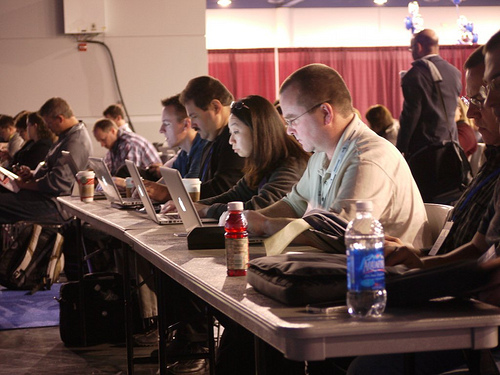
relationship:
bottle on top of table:
[221, 198, 251, 278] [51, 192, 498, 374]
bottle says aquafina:
[343, 198, 387, 319] [359, 258, 384, 271]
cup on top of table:
[77, 168, 99, 204] [51, 192, 498, 374]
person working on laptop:
[218, 62, 432, 250] [156, 162, 263, 245]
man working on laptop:
[180, 75, 240, 203] [122, 158, 219, 224]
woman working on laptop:
[189, 94, 308, 227] [122, 158, 219, 224]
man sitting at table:
[180, 75, 240, 203] [51, 192, 498, 374]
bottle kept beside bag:
[343, 198, 387, 319] [246, 252, 487, 314]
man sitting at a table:
[180, 75, 240, 203] [51, 192, 498, 374]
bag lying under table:
[56, 269, 143, 353] [51, 192, 498, 374]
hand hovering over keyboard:
[221, 210, 269, 236] [197, 216, 271, 246]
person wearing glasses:
[218, 62, 432, 250] [281, 99, 337, 130]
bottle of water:
[343, 198, 387, 319] [346, 218, 386, 317]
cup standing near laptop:
[77, 168, 99, 204] [87, 157, 159, 210]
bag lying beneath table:
[56, 269, 143, 353] [51, 192, 498, 374]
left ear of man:
[209, 98, 223, 115] [180, 75, 240, 203]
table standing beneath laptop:
[51, 192, 498, 374] [122, 158, 219, 224]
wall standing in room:
[2, 0, 205, 162] [0, 0, 499, 374]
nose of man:
[190, 117, 197, 128] [180, 75, 240, 203]